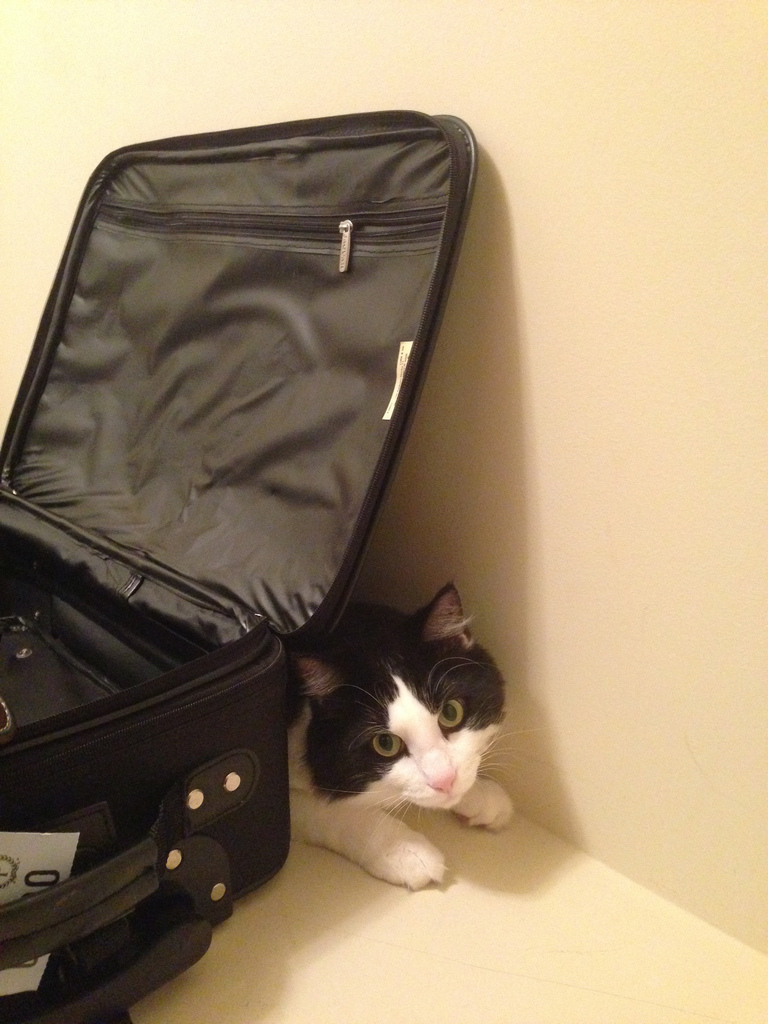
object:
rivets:
[165, 767, 245, 898]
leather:
[0, 107, 480, 651]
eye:
[435, 688, 468, 734]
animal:
[279, 581, 510, 890]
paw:
[363, 818, 445, 890]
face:
[376, 654, 488, 801]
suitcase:
[0, 112, 475, 1019]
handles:
[0, 759, 263, 961]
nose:
[425, 755, 457, 794]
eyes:
[371, 699, 466, 757]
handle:
[0, 751, 263, 986]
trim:
[185, 748, 259, 836]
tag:
[377, 337, 415, 422]